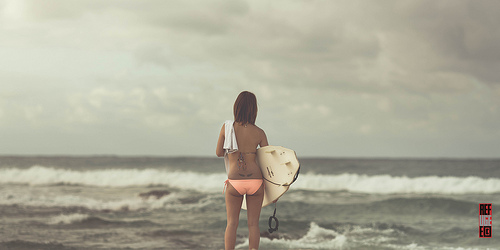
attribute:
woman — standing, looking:
[213, 85, 301, 244]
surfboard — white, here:
[240, 140, 303, 208]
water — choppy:
[0, 153, 499, 247]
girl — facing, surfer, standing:
[214, 88, 302, 249]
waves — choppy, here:
[4, 161, 499, 228]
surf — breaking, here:
[232, 212, 424, 248]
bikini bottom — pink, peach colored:
[229, 176, 266, 200]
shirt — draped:
[222, 119, 241, 154]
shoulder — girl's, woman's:
[222, 122, 238, 132]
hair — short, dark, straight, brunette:
[231, 90, 260, 124]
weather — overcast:
[5, 0, 494, 240]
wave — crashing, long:
[3, 158, 500, 223]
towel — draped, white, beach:
[222, 118, 238, 157]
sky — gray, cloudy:
[5, 5, 494, 155]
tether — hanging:
[267, 203, 279, 235]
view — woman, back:
[207, 85, 303, 243]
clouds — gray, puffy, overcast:
[7, 5, 500, 146]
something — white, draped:
[223, 117, 235, 155]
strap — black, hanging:
[267, 210, 282, 237]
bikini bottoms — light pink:
[228, 171, 266, 200]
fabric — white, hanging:
[222, 118, 239, 155]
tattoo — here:
[235, 171, 256, 178]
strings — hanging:
[234, 152, 248, 169]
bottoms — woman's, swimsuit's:
[226, 177, 269, 194]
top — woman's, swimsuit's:
[227, 144, 258, 163]